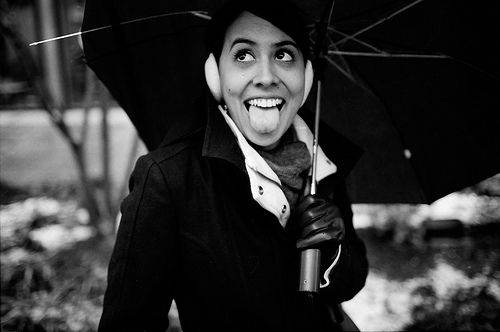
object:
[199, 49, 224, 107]
muff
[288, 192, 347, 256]
glove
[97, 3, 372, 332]
woman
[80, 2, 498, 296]
umbrella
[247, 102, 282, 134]
tongue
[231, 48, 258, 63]
eye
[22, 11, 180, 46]
wire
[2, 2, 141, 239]
tree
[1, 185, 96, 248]
snow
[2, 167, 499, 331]
ground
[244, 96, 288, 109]
teeth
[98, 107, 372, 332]
jacket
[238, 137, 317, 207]
scarf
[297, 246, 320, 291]
base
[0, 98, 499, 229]
pond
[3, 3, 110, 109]
wall